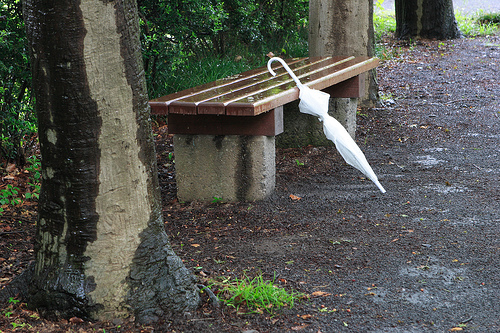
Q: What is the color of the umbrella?
A: White.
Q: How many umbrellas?
A: One.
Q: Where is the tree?
A: By the umbrella.